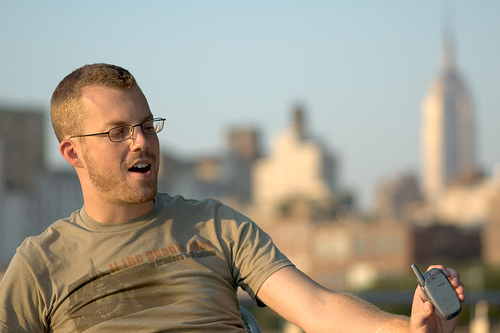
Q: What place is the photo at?
A: It is at the city.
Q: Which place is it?
A: It is a city.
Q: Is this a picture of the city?
A: Yes, it is showing the city.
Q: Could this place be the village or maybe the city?
A: It is the city.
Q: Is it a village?
A: No, it is a city.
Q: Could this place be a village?
A: No, it is a city.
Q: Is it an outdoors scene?
A: Yes, it is outdoors.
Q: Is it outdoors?
A: Yes, it is outdoors.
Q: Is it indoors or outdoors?
A: It is outdoors.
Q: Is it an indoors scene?
A: No, it is outdoors.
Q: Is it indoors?
A: No, it is outdoors.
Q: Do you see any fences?
A: No, there are no fences.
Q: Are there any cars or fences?
A: No, there are no fences or cars.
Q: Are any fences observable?
A: No, there are no fences.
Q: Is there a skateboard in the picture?
A: No, there are no skateboards.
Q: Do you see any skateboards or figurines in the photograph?
A: No, there are no skateboards or figurines.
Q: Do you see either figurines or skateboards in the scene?
A: No, there are no skateboards or figurines.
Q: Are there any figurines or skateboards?
A: No, there are no skateboards or figurines.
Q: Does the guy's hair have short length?
A: Yes, the hair is short.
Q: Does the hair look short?
A: Yes, the hair is short.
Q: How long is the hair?
A: The hair is short.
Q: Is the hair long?
A: No, the hair is short.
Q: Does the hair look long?
A: No, the hair is short.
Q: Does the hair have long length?
A: No, the hair is short.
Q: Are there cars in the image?
A: No, there are no cars.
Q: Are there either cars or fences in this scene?
A: No, there are no cars or fences.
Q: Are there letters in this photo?
A: Yes, there are letters.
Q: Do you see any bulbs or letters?
A: Yes, there are letters.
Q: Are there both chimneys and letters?
A: No, there are letters but no chimneys.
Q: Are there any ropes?
A: No, there are no ropes.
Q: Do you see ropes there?
A: No, there are no ropes.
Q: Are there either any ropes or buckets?
A: No, there are no ropes or buckets.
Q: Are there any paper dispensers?
A: No, there are no paper dispensers.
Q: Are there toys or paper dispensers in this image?
A: No, there are no paper dispensers or toys.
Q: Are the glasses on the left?
A: Yes, the glasses are on the left of the image.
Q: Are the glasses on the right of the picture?
A: No, the glasses are on the left of the image.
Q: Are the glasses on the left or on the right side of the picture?
A: The glasses are on the left of the image.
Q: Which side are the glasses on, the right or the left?
A: The glasses are on the left of the image.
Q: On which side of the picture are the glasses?
A: The glasses are on the left of the image.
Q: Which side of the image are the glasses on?
A: The glasses are on the left of the image.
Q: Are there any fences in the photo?
A: No, there are no fences.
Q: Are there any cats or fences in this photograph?
A: No, there are no fences or cats.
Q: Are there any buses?
A: No, there are no buses.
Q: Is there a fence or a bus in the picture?
A: No, there are no buses or fences.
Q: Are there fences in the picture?
A: No, there are no fences.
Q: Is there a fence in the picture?
A: No, there are no fences.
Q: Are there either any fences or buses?
A: No, there are no fences or buses.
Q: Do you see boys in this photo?
A: No, there are no boys.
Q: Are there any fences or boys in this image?
A: No, there are no boys or fences.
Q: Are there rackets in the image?
A: No, there are no rackets.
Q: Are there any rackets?
A: No, there are no rackets.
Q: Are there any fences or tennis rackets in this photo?
A: No, there are no tennis rackets or fences.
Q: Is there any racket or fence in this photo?
A: No, there are no rackets or fences.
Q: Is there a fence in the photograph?
A: No, there are no fences.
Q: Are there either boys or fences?
A: No, there are no fences or boys.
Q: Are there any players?
A: No, there are no players.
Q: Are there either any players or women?
A: No, there are no players or women.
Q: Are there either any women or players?
A: No, there are no players or women.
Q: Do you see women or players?
A: No, there are no players or women.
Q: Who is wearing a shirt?
A: The guy is wearing a shirt.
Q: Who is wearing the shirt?
A: The guy is wearing a shirt.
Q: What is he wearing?
A: The guy is wearing a shirt.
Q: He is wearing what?
A: The guy is wearing a shirt.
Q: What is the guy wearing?
A: The guy is wearing a shirt.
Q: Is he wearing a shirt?
A: Yes, the guy is wearing a shirt.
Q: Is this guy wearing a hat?
A: No, the guy is wearing a shirt.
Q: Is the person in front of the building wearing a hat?
A: No, the guy is wearing a shirt.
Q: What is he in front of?
A: The guy is in front of the building.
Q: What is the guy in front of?
A: The guy is in front of the building.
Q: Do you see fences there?
A: No, there are no fences.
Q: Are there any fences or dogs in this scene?
A: No, there are no fences or dogs.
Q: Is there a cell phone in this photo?
A: Yes, there is a cell phone.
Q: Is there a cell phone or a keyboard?
A: Yes, there is a cell phone.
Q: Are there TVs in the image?
A: No, there are no tvs.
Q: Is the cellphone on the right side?
A: Yes, the cellphone is on the right of the image.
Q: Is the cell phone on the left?
A: No, the cell phone is on the right of the image.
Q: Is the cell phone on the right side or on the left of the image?
A: The cell phone is on the right of the image.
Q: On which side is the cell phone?
A: The cell phone is on the right of the image.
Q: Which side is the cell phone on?
A: The cell phone is on the right of the image.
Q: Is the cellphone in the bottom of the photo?
A: Yes, the cellphone is in the bottom of the image.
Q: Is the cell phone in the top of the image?
A: No, the cell phone is in the bottom of the image.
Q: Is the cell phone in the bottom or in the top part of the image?
A: The cell phone is in the bottom of the image.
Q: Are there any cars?
A: No, there are no cars.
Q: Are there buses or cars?
A: No, there are no cars or buses.